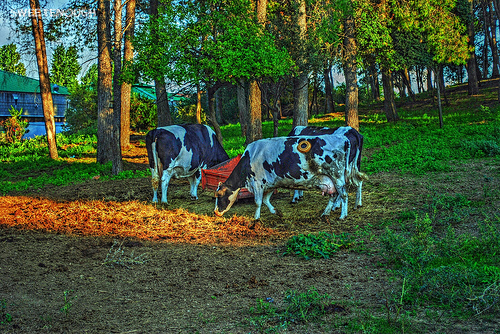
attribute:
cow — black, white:
[208, 131, 348, 225]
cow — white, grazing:
[141, 121, 237, 206]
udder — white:
[316, 176, 338, 196]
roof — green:
[0, 69, 73, 99]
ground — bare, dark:
[0, 76, 500, 333]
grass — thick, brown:
[31, 105, 494, 167]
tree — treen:
[205, 0, 290, 134]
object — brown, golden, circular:
[295, 139, 311, 155]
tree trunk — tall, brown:
[89, 4, 126, 180]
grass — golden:
[18, 187, 307, 249]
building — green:
[6, 73, 80, 135]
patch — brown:
[416, 91, 488, 114]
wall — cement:
[17, 122, 68, 142]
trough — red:
[197, 147, 277, 198]